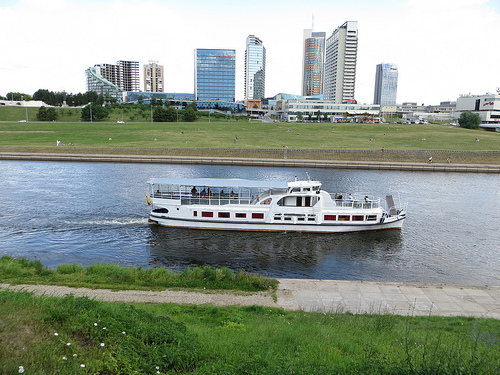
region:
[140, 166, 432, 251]
a boat in the river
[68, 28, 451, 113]
a nice skyline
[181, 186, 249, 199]
passengers on the boat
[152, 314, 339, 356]
grass on the side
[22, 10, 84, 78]
clouds in the sky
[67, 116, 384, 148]
grass in the foreground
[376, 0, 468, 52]
clouds by big buildings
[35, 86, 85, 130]
trees in the background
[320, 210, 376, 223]
windows off the boat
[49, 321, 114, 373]
white flowers in the grass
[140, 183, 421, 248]
boat with passengers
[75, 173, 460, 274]
boat moving in the water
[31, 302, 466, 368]
grass beside the sidewalk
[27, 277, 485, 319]
sidewalk beside the grass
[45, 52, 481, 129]
view of the city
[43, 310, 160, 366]
weeds in the grass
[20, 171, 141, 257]
water that boat is in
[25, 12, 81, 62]
bright sky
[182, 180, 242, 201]
people on a boat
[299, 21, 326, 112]
very tall building in picture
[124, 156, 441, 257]
a white boat in river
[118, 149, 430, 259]
a party boat having fun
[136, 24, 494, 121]
a skyline of things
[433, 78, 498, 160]
a different type of building in the right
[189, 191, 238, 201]
people on the boat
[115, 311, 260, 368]
grass in front of the boat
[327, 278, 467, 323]
a sidewalk for people to walk on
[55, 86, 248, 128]
lamp posts in the back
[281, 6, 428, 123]
some really tall buildings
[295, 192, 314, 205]
coulple of doors in the boat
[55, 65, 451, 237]
a boat with lots of people on deck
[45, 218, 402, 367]
lots of grass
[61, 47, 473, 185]
buildings in the background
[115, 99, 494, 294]
a boat going down a river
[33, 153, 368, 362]
dirty water in a river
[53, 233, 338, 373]
lush, green grass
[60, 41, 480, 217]
aesthetically appealing buildings with glass windows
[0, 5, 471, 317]
boat in an urban area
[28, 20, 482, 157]
a clear sky with no clouds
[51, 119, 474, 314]
a white boat with passengers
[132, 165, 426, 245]
a boat on a canal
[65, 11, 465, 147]
a city skyline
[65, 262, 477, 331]
a path along the water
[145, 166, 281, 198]
a canopy to protect passengers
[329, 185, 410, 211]
people enjoying the ride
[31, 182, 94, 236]
still canal water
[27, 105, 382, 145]
a park by the canal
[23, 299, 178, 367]
grass and flowers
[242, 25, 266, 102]
a skyscraper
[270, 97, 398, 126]
a white building with lots of windows